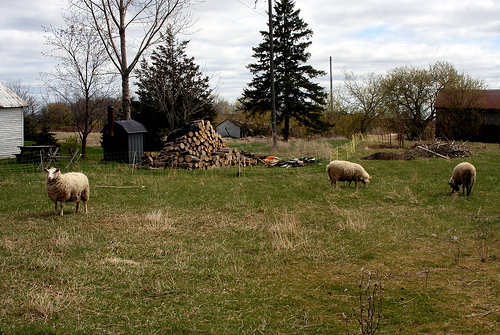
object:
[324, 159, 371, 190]
sheep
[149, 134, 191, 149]
logs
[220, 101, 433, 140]
branch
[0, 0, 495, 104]
clouds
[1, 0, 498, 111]
sky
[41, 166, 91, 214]
sheep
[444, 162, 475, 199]
sheep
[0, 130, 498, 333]
grass